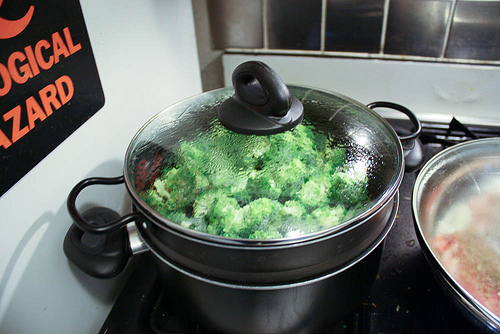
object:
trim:
[217, 33, 497, 80]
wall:
[214, 49, 499, 131]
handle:
[60, 206, 132, 281]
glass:
[414, 128, 499, 333]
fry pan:
[407, 127, 499, 332]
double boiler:
[62, 52, 428, 333]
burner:
[134, 274, 379, 331]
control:
[436, 117, 478, 152]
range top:
[66, 56, 421, 333]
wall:
[0, 0, 221, 334]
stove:
[96, 116, 500, 334]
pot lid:
[104, 68, 416, 243]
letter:
[0, 0, 92, 137]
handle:
[366, 94, 425, 148]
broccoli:
[137, 117, 375, 242]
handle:
[215, 57, 307, 137]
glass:
[153, 85, 389, 245]